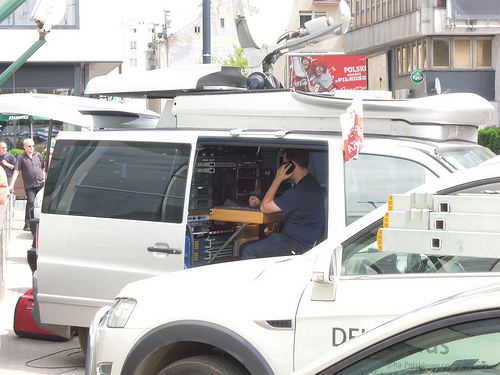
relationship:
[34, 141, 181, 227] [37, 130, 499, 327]
window on vehicle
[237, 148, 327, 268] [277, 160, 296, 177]
man on phone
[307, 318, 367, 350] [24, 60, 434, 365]
de on vehicle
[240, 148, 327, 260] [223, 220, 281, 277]
man in pants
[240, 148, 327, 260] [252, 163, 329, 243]
man in shirt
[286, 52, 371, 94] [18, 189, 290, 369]
poster beside road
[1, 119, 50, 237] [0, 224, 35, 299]
man on road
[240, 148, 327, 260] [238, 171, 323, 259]
man dressed in black outfit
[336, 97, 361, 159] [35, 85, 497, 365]
poster in vehicle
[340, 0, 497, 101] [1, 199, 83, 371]
building adjacent to road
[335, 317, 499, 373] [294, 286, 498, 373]
window on vehicle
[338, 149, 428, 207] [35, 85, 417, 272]
window on vehicle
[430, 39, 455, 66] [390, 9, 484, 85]
window on building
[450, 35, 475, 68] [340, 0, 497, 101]
window on building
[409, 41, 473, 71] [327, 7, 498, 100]
window on building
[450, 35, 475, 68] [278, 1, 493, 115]
window on building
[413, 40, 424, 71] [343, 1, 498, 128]
glass window on building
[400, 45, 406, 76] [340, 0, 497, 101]
window on building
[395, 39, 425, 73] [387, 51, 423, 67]
window on building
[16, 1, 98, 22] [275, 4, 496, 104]
window on building